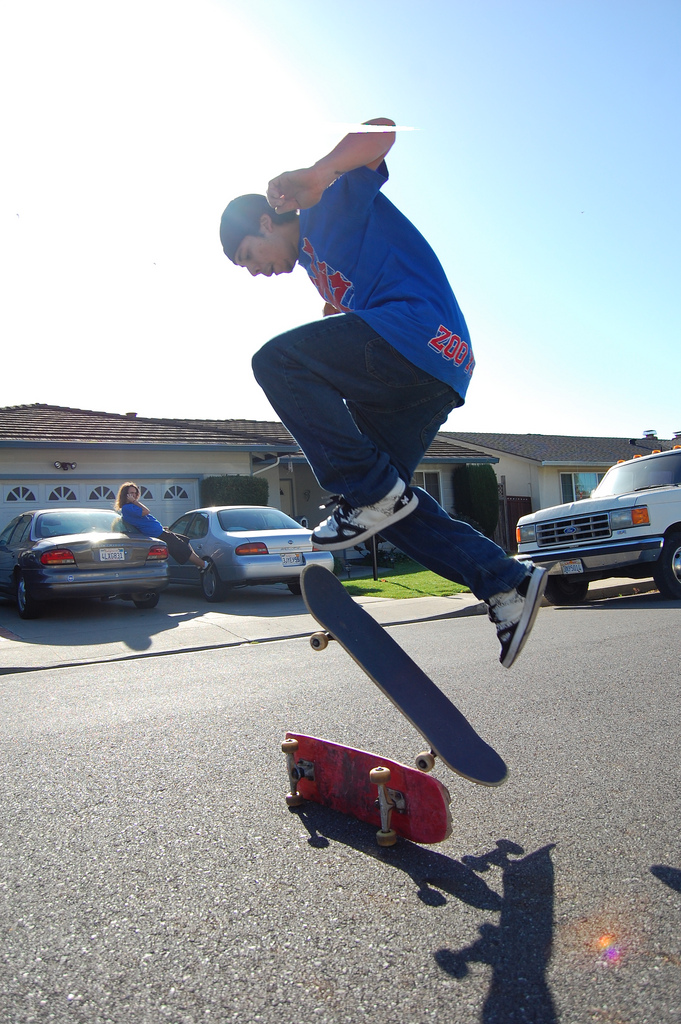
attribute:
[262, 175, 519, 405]
shirt — blue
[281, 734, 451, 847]
skateboard — red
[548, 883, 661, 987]
spray paiint — purple, orange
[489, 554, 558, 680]
shoe — white, blue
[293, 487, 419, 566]
shoe — white, blue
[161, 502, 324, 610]
car — silver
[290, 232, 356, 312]
writing — red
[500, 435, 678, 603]
truck — white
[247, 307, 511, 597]
jeans — blue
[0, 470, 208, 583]
garage door — white